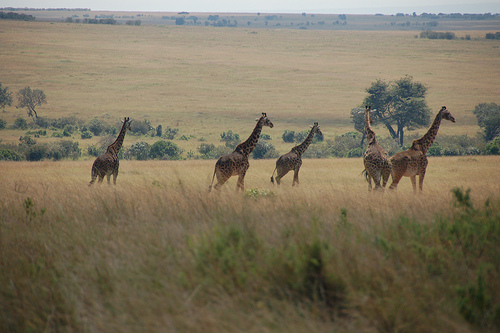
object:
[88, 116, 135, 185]
giraffe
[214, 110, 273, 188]
giraffe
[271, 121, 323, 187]
giraffe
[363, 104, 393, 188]
giraffe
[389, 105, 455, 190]
giraffe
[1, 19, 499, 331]
plain